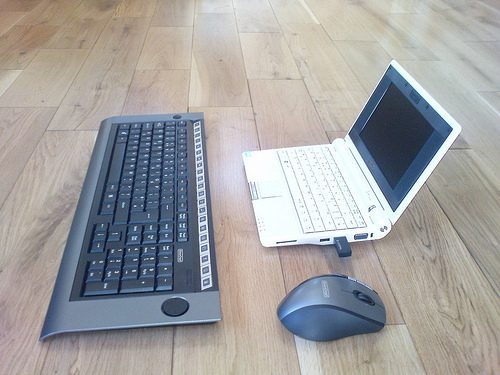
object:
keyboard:
[40, 113, 223, 340]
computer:
[241, 57, 464, 247]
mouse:
[276, 272, 387, 343]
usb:
[335, 237, 352, 258]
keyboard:
[277, 148, 368, 234]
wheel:
[357, 289, 373, 303]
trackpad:
[256, 176, 284, 200]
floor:
[1, 0, 498, 374]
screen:
[359, 79, 436, 190]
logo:
[320, 277, 331, 298]